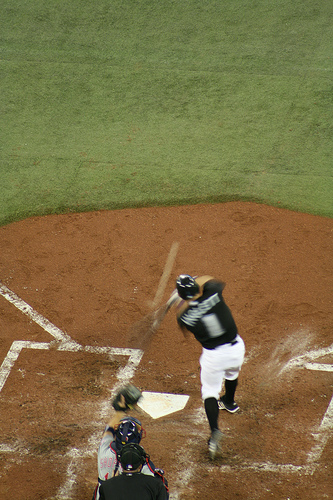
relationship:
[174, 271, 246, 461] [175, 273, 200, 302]
man wearing helmet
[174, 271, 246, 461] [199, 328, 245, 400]
man wearing pants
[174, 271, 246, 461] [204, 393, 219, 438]
man wearing sock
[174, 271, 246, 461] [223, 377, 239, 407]
man wearing sock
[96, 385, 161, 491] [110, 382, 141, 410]
man has mitt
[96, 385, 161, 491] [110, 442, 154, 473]
man wearing vest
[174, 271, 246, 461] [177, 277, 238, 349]
man wearing shirt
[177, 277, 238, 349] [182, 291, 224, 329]
shirt has lettering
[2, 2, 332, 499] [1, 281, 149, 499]
field has line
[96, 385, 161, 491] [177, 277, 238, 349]
man wearing shirt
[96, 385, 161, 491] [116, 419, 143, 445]
man wearing helmet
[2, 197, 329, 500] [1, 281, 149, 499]
dirt has line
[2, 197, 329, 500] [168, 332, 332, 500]
dirt has line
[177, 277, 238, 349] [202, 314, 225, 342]
shirt has 1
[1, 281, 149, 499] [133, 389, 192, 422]
line around home base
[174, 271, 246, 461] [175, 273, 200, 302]
man has helmet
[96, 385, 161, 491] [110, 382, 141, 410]
man holding up mitt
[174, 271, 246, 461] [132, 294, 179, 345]
man swinging bat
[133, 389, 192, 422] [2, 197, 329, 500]
home base sitting in dirt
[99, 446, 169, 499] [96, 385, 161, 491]
umpire behind man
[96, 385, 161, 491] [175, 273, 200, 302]
man wearing helmet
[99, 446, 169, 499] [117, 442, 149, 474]
umpire wearing head protection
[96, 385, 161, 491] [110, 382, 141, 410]
man wearing mitt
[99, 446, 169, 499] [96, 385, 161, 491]
umpire stands behind man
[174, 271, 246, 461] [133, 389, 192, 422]
man standing near home base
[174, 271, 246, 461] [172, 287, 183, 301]
man has hand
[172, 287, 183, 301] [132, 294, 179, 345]
hand has bat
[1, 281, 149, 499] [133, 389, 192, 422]
line drawn by home base